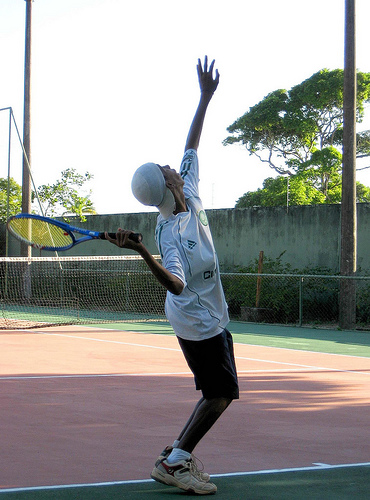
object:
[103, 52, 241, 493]
man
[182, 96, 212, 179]
arm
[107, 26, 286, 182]
air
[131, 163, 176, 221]
hat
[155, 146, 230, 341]
shirt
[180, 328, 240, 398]
shorts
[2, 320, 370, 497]
tennis court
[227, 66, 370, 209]
tree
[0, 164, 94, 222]
tree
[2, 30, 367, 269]
background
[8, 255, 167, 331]
net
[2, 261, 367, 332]
fence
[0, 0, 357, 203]
sky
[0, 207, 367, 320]
wall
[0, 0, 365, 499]
scene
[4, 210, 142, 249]
tennis racket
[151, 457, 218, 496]
sneakers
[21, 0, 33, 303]
pole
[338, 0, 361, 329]
pole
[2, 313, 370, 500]
floor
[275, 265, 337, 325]
bushes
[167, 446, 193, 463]
sock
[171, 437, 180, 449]
sock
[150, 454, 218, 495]
feet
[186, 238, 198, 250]
logo